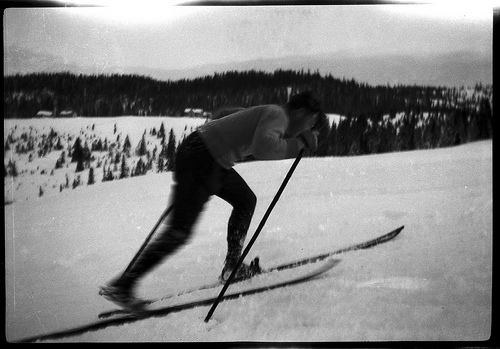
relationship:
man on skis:
[96, 88, 336, 311] [1, 222, 428, 347]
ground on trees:
[1, 114, 500, 347] [3, 124, 177, 176]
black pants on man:
[106, 127, 256, 304] [96, 88, 336, 311]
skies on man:
[8, 258, 341, 344] [96, 88, 336, 311]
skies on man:
[8, 257, 336, 340] [96, 88, 336, 311]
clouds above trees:
[0, 3, 490, 89] [2, 69, 487, 201]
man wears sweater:
[96, 88, 336, 311] [194, 102, 290, 171]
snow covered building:
[56, 107, 73, 114] [58, 110, 78, 117]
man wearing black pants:
[97, 91, 327, 307] [105, 130, 257, 291]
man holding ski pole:
[97, 91, 327, 307] [247, 125, 299, 310]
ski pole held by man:
[204, 128, 313, 322] [97, 91, 327, 307]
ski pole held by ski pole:
[123, 205, 169, 285] [204, 128, 313, 322]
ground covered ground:
[1, 117, 462, 346] [1, 114, 500, 347]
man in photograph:
[97, 91, 327, 307] [6, 10, 498, 340]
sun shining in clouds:
[58, 0, 199, 31] [0, 0, 490, 86]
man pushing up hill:
[97, 91, 327, 307] [24, 145, 490, 344]